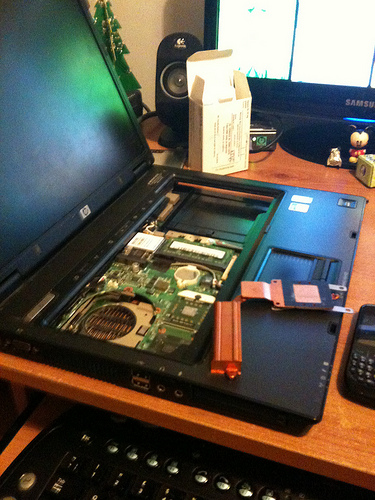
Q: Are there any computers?
A: Yes, there is a computer.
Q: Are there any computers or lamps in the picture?
A: Yes, there is a computer.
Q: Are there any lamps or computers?
A: Yes, there is a computer.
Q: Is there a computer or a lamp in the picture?
A: Yes, there is a computer.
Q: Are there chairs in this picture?
A: No, there are no chairs.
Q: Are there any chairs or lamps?
A: No, there are no chairs or lamps.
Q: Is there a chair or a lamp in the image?
A: No, there are no chairs or lamps.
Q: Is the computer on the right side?
A: Yes, the computer is on the right of the image.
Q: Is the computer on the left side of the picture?
A: No, the computer is on the right of the image.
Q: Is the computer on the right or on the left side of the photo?
A: The computer is on the right of the image.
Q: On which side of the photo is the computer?
A: The computer is on the right of the image.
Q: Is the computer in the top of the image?
A: Yes, the computer is in the top of the image.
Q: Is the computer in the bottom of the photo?
A: No, the computer is in the top of the image.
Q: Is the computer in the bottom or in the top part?
A: The computer is in the top of the image.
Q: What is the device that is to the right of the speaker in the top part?
A: The device is a computer.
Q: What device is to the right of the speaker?
A: The device is a computer.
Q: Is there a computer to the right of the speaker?
A: Yes, there is a computer to the right of the speaker.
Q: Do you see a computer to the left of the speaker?
A: No, the computer is to the right of the speaker.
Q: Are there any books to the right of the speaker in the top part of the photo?
A: No, there is a computer to the right of the speaker.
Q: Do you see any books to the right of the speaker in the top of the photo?
A: No, there is a computer to the right of the speaker.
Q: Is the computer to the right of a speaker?
A: Yes, the computer is to the right of a speaker.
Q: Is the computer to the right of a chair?
A: No, the computer is to the right of a speaker.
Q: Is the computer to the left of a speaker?
A: No, the computer is to the right of a speaker.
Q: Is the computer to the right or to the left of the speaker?
A: The computer is to the right of the speaker.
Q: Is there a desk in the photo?
A: Yes, there is a desk.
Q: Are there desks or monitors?
A: Yes, there is a desk.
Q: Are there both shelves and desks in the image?
A: No, there is a desk but no shelves.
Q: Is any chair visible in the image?
A: No, there are no chairs.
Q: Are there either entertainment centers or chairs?
A: No, there are no chairs or entertainment centers.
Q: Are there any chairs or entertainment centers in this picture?
A: No, there are no chairs or entertainment centers.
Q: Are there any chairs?
A: No, there are no chairs.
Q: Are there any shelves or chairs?
A: No, there are no chairs or shelves.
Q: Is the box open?
A: Yes, the box is open.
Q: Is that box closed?
A: No, the box is open.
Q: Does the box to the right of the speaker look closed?
A: No, the box is open.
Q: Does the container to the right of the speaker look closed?
A: No, the box is open.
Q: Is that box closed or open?
A: The box is open.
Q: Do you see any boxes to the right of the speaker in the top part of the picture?
A: Yes, there is a box to the right of the speaker.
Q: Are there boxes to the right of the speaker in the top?
A: Yes, there is a box to the right of the speaker.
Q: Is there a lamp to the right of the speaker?
A: No, there is a box to the right of the speaker.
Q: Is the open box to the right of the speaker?
A: Yes, the box is to the right of the speaker.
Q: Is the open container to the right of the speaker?
A: Yes, the box is to the right of the speaker.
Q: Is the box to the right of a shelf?
A: No, the box is to the right of the speaker.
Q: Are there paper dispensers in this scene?
A: No, there are no paper dispensers.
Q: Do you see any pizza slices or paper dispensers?
A: No, there are no paper dispensers or pizza slices.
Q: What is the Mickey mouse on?
A: The Mickey mouse is on the desk.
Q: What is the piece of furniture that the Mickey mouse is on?
A: The piece of furniture is a desk.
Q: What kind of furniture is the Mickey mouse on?
A: The Mickey mouse is on the desk.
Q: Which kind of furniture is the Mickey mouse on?
A: The Mickey mouse is on the desk.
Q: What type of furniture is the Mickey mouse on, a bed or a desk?
A: The Mickey mouse is on a desk.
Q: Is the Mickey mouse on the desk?
A: Yes, the Mickey mouse is on the desk.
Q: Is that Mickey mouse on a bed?
A: No, the Mickey mouse is on the desk.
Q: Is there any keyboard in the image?
A: Yes, there is a keyboard.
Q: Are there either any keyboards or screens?
A: Yes, there is a keyboard.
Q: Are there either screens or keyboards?
A: Yes, there is a keyboard.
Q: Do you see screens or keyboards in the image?
A: Yes, there is a keyboard.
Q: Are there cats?
A: No, there are no cats.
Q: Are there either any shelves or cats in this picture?
A: No, there are no cats or shelves.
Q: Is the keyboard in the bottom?
A: Yes, the keyboard is in the bottom of the image.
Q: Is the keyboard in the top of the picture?
A: No, the keyboard is in the bottom of the image.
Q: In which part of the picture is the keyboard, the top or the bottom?
A: The keyboard is in the bottom of the image.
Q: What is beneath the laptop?
A: The keyboard is beneath the laptop.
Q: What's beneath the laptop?
A: The keyboard is beneath the laptop.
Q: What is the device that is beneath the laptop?
A: The device is a keyboard.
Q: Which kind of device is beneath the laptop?
A: The device is a keyboard.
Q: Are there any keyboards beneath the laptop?
A: Yes, there is a keyboard beneath the laptop.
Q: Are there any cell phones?
A: Yes, there is a cell phone.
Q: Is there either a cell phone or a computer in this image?
A: Yes, there is a cell phone.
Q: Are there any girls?
A: No, there are no girls.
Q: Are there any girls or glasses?
A: No, there are no girls or glasses.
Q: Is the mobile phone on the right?
A: Yes, the mobile phone is on the right of the image.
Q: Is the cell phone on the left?
A: No, the cell phone is on the right of the image.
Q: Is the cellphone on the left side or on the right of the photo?
A: The cellphone is on the right of the image.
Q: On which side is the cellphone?
A: The cellphone is on the right of the image.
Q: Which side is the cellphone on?
A: The cellphone is on the right of the image.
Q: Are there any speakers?
A: Yes, there is a speaker.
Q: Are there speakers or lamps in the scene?
A: Yes, there is a speaker.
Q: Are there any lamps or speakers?
A: Yes, there is a speaker.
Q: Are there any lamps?
A: No, there are no lamps.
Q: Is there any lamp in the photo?
A: No, there are no lamps.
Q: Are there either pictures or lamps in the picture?
A: No, there are no lamps or pictures.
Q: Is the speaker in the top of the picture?
A: Yes, the speaker is in the top of the image.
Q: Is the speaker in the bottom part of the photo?
A: No, the speaker is in the top of the image.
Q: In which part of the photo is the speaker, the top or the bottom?
A: The speaker is in the top of the image.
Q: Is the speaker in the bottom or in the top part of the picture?
A: The speaker is in the top of the image.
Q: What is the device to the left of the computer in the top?
A: The device is a speaker.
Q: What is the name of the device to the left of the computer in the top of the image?
A: The device is a speaker.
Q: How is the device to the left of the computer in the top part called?
A: The device is a speaker.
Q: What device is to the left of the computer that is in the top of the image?
A: The device is a speaker.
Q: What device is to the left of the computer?
A: The device is a speaker.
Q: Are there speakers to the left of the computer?
A: Yes, there is a speaker to the left of the computer.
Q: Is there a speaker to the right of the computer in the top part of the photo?
A: No, the speaker is to the left of the computer.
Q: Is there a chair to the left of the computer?
A: No, there is a speaker to the left of the computer.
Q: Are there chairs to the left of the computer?
A: No, there is a speaker to the left of the computer.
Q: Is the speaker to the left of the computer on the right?
A: Yes, the speaker is to the left of the computer.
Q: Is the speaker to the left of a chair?
A: No, the speaker is to the left of the computer.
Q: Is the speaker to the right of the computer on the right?
A: No, the speaker is to the left of the computer.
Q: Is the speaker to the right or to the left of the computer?
A: The speaker is to the left of the computer.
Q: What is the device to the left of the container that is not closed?
A: The device is a speaker.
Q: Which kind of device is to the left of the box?
A: The device is a speaker.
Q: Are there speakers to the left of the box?
A: Yes, there is a speaker to the left of the box.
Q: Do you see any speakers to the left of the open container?
A: Yes, there is a speaker to the left of the box.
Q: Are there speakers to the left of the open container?
A: Yes, there is a speaker to the left of the box.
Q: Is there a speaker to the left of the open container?
A: Yes, there is a speaker to the left of the box.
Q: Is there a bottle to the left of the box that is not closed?
A: No, there is a speaker to the left of the box.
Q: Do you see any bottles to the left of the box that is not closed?
A: No, there is a speaker to the left of the box.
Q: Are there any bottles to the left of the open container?
A: No, there is a speaker to the left of the box.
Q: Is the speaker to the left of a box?
A: Yes, the speaker is to the left of a box.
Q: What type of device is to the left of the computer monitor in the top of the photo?
A: The device is a speaker.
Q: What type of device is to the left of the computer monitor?
A: The device is a speaker.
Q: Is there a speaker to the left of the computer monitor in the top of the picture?
A: Yes, there is a speaker to the left of the computer monitor.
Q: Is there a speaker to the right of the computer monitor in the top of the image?
A: No, the speaker is to the left of the computer monitor.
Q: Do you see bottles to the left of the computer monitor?
A: No, there is a speaker to the left of the computer monitor.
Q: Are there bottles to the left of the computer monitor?
A: No, there is a speaker to the left of the computer monitor.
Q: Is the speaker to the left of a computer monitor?
A: Yes, the speaker is to the left of a computer monitor.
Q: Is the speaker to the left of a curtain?
A: No, the speaker is to the left of a computer monitor.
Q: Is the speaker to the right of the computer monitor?
A: No, the speaker is to the left of the computer monitor.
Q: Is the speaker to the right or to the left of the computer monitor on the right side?
A: The speaker is to the left of the computer monitor.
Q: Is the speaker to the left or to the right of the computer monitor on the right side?
A: The speaker is to the left of the computer monitor.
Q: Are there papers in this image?
A: No, there are no papers.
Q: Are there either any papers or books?
A: No, there are no papers or books.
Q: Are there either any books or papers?
A: No, there are no papers or books.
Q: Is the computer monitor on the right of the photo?
A: Yes, the computer monitor is on the right of the image.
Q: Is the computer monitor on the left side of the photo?
A: No, the computer monitor is on the right of the image.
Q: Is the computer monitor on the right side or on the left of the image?
A: The computer monitor is on the right of the image.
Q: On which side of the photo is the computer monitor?
A: The computer monitor is on the right of the image.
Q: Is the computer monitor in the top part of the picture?
A: Yes, the computer monitor is in the top of the image.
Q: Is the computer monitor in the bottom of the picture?
A: No, the computer monitor is in the top of the image.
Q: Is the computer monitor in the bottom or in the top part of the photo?
A: The computer monitor is in the top of the image.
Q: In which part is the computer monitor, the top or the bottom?
A: The computer monitor is in the top of the image.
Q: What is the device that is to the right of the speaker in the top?
A: The device is a computer monitor.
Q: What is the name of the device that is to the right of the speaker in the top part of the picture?
A: The device is a computer monitor.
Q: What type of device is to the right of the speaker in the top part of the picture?
A: The device is a computer monitor.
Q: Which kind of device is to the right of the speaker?
A: The device is a computer monitor.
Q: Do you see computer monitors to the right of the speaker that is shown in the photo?
A: Yes, there is a computer monitor to the right of the speaker.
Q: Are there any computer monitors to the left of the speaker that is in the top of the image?
A: No, the computer monitor is to the right of the speaker.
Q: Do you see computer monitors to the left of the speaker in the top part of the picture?
A: No, the computer monitor is to the right of the speaker.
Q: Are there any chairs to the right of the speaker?
A: No, there is a computer monitor to the right of the speaker.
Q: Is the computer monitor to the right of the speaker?
A: Yes, the computer monitor is to the right of the speaker.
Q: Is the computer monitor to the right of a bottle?
A: No, the computer monitor is to the right of the speaker.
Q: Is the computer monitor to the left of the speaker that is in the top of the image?
A: No, the computer monitor is to the right of the speaker.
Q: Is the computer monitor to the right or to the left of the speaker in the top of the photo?
A: The computer monitor is to the right of the speaker.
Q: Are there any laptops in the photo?
A: Yes, there is a laptop.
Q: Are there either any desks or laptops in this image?
A: Yes, there is a laptop.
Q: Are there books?
A: No, there are no books.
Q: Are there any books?
A: No, there are no books.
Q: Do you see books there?
A: No, there are no books.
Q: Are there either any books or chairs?
A: No, there are no books or chairs.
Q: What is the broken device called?
A: The device is a laptop.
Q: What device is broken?
A: The device is a laptop.